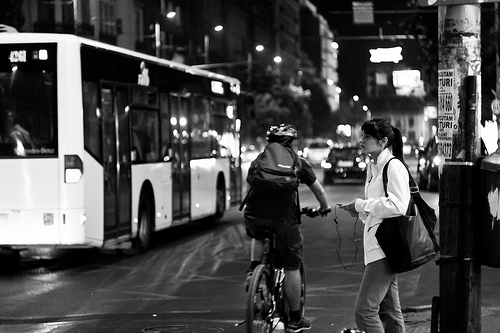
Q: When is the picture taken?
A: At night.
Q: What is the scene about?
A: A busy street.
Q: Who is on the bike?
A: A man.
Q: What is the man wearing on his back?
A: A backpack.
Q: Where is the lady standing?
A: Near the pole.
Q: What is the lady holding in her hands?
A: Headphones.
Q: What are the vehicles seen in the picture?
A: Bus and cars.